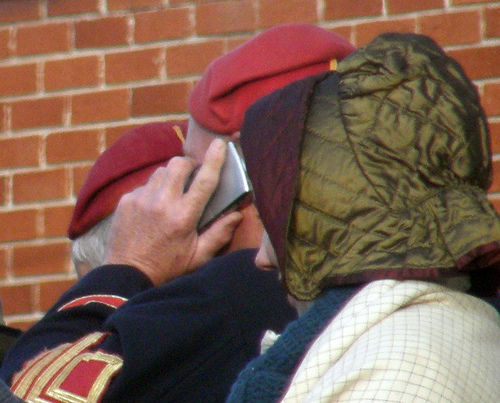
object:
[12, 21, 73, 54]
brick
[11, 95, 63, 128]
brick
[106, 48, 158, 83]
brick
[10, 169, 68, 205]
brick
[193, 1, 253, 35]
brick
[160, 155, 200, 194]
finger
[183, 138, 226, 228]
finger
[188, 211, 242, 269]
finger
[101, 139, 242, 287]
hand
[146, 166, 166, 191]
finger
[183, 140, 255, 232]
cell phone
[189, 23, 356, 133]
cap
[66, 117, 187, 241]
cap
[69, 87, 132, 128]
brick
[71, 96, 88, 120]
part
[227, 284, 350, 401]
blue scarf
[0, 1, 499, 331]
building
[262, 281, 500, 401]
jacket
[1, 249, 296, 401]
jacket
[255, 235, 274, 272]
nose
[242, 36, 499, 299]
hood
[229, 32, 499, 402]
woman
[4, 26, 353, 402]
man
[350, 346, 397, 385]
edge